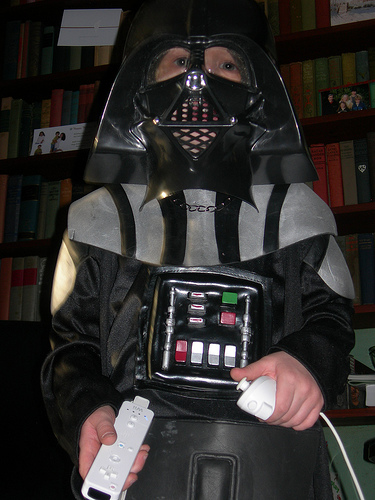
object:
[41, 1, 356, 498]
boy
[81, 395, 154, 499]
controller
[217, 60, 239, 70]
eye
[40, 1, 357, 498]
costume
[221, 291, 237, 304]
buttons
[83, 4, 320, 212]
mask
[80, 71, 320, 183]
bottom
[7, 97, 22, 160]
books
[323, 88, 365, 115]
family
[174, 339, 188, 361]
switch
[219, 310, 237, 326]
buttons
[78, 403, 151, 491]
hand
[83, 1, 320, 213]
helmet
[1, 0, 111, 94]
shelf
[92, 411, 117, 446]
thumb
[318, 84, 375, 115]
photo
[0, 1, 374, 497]
bookshelf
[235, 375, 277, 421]
joystick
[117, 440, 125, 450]
directional pad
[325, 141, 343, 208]
book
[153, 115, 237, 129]
chain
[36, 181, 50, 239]
book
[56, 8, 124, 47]
paper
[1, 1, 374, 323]
collection